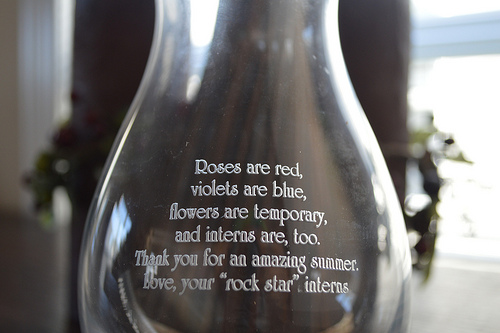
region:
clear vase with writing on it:
[75, 0, 414, 331]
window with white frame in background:
[405, 0, 499, 275]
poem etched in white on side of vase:
[132, 157, 359, 294]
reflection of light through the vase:
[184, 0, 220, 110]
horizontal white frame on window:
[411, 11, 498, 61]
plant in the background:
[22, 83, 115, 214]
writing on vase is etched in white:
[133, 158, 360, 294]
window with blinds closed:
[3, 0, 73, 226]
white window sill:
[431, 250, 499, 273]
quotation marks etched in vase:
[218, 269, 227, 279]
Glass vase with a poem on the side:
[75, 0, 410, 330]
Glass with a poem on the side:
[70, 0, 415, 330]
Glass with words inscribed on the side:
[75, 0, 415, 325]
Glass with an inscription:
[75, 0, 410, 330]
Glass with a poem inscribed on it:
[70, 5, 415, 330]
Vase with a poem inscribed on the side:
[70, 0, 410, 325]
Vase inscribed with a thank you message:
[70, 0, 410, 330]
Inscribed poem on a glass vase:
[75, 0, 410, 330]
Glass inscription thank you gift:
[75, 0, 410, 325]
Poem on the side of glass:
[130, 153, 357, 298]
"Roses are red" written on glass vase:
[192, 158, 304, 176]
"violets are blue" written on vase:
[187, 180, 305, 203]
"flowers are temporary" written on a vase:
[166, 200, 328, 229]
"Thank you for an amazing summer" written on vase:
[130, 250, 360, 270]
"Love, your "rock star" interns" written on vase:
[141, 271, 351, 297]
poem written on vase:
[134, 157, 359, 304]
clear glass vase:
[80, 1, 415, 332]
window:
[409, 4, 494, 280]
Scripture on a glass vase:
[132, 114, 369, 328]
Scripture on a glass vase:
[166, 136, 313, 209]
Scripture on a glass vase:
[163, 199, 328, 250]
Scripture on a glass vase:
[128, 243, 372, 300]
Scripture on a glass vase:
[172, 152, 318, 247]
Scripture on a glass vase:
[148, 189, 345, 304]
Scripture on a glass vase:
[111, 115, 364, 313]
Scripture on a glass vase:
[122, 183, 386, 319]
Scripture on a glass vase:
[145, 155, 302, 277]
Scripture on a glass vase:
[148, 145, 339, 306]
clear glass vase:
[71, 3, 421, 330]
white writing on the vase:
[131, 140, 362, 307]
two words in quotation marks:
[218, 270, 301, 296]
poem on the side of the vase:
[124, 149, 366, 308]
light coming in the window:
[408, 53, 498, 265]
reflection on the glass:
[86, 196, 148, 292]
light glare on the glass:
[182, 0, 219, 47]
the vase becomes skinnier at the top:
[81, 0, 423, 330]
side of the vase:
[319, 7, 433, 332]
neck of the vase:
[152, 0, 357, 43]